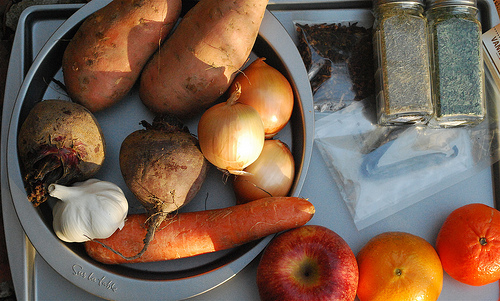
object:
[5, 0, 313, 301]
tin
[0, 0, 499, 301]
tray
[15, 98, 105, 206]
yam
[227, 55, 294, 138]
onion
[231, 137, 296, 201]
onion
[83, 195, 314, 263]
carrot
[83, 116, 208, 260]
beet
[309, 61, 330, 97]
herbs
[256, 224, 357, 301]
apple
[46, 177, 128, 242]
garlic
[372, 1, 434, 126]
shaker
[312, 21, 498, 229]
packet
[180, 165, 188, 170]
dirt